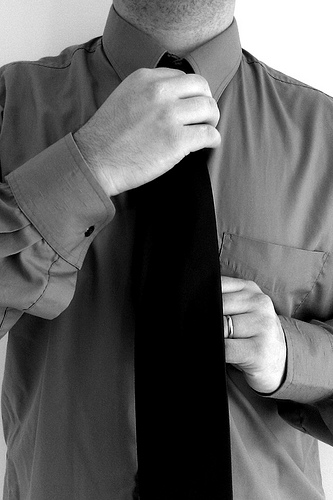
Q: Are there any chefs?
A: No, there are no chefs.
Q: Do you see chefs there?
A: No, there are no chefs.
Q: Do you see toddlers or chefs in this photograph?
A: No, there are no chefs or toddlers.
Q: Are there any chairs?
A: No, there are no chairs.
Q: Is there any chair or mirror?
A: No, there are no chairs or mirrors.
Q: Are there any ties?
A: Yes, there is a tie.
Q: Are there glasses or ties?
A: Yes, there is a tie.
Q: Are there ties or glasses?
A: Yes, there is a tie.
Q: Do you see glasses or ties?
A: Yes, there is a tie.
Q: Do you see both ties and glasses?
A: No, there is a tie but no glasses.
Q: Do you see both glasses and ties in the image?
A: No, there is a tie but no glasses.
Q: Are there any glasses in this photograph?
A: No, there are no glasses.